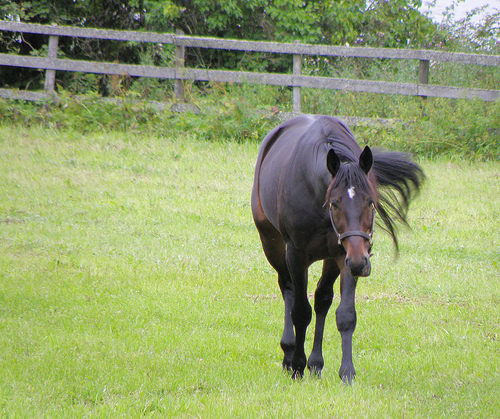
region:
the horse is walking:
[250, 116, 410, 374]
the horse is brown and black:
[252, 100, 415, 377]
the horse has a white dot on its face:
[342, 180, 355, 208]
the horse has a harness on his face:
[325, 214, 382, 250]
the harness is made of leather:
[342, 227, 381, 255]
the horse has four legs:
[267, 257, 368, 383]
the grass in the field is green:
[20, 196, 233, 369]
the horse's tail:
[370, 142, 434, 253]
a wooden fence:
[4, 10, 496, 149]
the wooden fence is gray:
[2, 10, 494, 135]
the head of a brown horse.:
[309, 136, 396, 271]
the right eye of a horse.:
[326, 193, 355, 228]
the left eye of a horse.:
[361, 191, 378, 221]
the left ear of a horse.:
[352, 128, 374, 179]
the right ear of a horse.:
[323, 146, 345, 187]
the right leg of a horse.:
[277, 248, 317, 388]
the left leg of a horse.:
[326, 256, 373, 397]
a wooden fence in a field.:
[0, 19, 498, 135]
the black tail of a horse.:
[348, 128, 427, 268]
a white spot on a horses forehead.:
[341, 183, 361, 205]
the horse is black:
[214, 107, 428, 366]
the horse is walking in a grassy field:
[2, 116, 457, 415]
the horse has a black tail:
[355, 142, 443, 244]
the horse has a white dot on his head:
[344, 180, 362, 209]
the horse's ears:
[311, 140, 380, 182]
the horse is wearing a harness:
[321, 195, 391, 258]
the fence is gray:
[7, 17, 498, 152]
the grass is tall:
[68, 272, 247, 364]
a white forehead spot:
[340, 176, 364, 206]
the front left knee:
[330, 300, 363, 333]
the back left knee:
[313, 281, 335, 311]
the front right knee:
[288, 290, 320, 329]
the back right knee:
[278, 276, 293, 298]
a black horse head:
[313, 140, 393, 277]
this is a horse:
[229, 112, 433, 394]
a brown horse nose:
[341, 250, 376, 282]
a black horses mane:
[329, 120, 455, 260]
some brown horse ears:
[323, 140, 380, 179]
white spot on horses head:
[347, 186, 356, 198]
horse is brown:
[248, 111, 425, 381]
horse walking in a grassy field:
[251, 110, 426, 382]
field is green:
[1, 127, 498, 414]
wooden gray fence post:
[44, 24, 56, 101]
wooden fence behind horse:
[0, 18, 497, 153]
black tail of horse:
[371, 152, 424, 258]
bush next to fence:
[383, 90, 498, 155]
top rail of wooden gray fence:
[1, 17, 498, 73]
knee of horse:
[335, 305, 357, 328]